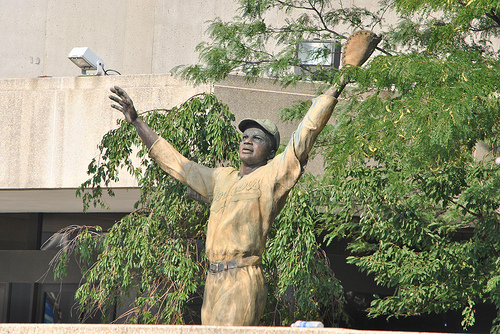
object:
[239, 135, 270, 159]
face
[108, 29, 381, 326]
portrait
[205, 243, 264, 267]
waist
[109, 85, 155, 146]
hand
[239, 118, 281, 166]
head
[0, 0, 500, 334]
building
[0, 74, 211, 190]
wall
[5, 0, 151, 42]
wall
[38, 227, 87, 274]
needles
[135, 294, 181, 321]
needles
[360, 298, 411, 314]
needles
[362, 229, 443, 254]
needles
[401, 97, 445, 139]
needles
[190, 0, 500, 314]
tree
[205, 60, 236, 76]
needles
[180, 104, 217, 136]
needles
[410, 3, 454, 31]
needles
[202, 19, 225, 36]
needles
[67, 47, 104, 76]
light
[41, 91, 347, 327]
tree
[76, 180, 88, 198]
leaves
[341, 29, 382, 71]
mitt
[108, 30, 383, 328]
player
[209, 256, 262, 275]
belt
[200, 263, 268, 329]
pants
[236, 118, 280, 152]
cap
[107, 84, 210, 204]
arm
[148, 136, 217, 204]
sleeve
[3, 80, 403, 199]
surface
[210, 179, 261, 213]
name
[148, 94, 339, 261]
shirt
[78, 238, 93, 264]
leaves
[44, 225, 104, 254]
branch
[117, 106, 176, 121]
branch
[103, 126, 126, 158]
leaves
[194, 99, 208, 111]
leaves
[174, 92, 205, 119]
branch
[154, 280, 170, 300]
branch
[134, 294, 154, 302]
leaves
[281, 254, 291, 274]
leaves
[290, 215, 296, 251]
branch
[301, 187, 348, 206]
branch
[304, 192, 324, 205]
leaves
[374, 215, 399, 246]
leaves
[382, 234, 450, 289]
branch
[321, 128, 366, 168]
branch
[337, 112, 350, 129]
leaves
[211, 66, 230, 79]
leaves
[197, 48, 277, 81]
branch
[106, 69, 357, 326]
statue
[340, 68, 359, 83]
hand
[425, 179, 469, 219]
leaves